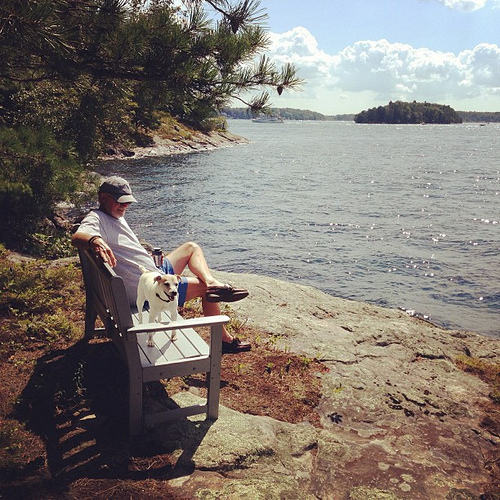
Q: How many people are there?
A: One.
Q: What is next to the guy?
A: Water.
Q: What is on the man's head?
A: Hat.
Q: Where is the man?
A: A bench.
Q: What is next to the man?
A: Dog.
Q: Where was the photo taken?
A: Near a body of water.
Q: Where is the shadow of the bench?
A: On the ground.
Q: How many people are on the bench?
A: One.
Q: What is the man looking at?
A: Dog.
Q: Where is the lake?
A: In front of the man.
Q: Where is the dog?
A: On the bench.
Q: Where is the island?
A: In the lake.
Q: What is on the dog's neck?
A: A collar.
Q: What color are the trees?
A: Green.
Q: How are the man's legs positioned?
A: Crossed.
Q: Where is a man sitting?
A: On a bench.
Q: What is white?
A: Clouds.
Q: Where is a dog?
A: On bench.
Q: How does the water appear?
A: Calm.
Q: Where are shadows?
A: On the ground.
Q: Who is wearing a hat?
A: The man.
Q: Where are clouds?
A: In the sky.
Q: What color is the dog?
A: White.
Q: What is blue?
A: The sky.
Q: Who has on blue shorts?
A: A man.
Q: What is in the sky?
A: Clouds.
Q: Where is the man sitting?
A: Beside a lake.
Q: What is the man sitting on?
A: A bench.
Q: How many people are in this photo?
A: 1.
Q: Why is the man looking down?
A: There's a dog.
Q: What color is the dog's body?
A: White.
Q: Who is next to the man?
A: The dog.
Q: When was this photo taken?
A: During the day.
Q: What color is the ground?
A: Brown.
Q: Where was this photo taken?
A: At a lake.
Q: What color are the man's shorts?
A: Blue.